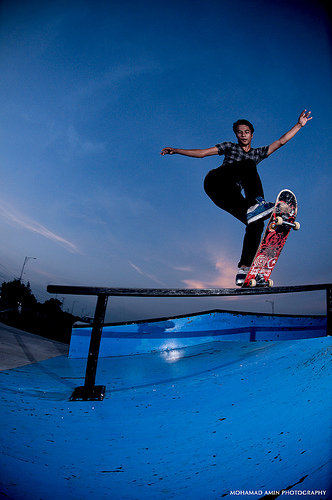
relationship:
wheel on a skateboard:
[274, 214, 283, 227] [243, 186, 298, 285]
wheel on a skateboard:
[292, 221, 299, 231] [243, 186, 298, 285]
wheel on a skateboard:
[264, 277, 276, 292] [243, 186, 298, 285]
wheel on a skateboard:
[247, 277, 259, 290] [243, 186, 298, 285]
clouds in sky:
[7, 185, 245, 291] [8, 10, 315, 291]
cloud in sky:
[61, 82, 105, 155] [1, 3, 330, 336]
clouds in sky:
[0, 185, 245, 301] [8, 9, 146, 263]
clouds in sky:
[0, 185, 245, 301] [1, 3, 330, 336]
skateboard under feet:
[158, 108, 314, 285] [244, 195, 275, 224]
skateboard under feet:
[158, 108, 314, 285] [235, 270, 275, 288]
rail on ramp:
[42, 275, 330, 327] [43, 263, 329, 419]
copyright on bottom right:
[223, 480, 330, 498] [200, 472, 329, 498]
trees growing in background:
[4, 276, 95, 348] [1, 222, 327, 360]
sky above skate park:
[0, 0, 332, 290] [12, 195, 330, 405]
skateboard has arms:
[241, 188, 301, 289] [152, 106, 330, 162]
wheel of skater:
[293, 221, 301, 231] [155, 79, 327, 297]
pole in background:
[17, 254, 38, 278] [2, 237, 328, 367]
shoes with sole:
[226, 203, 308, 258] [228, 276, 276, 289]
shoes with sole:
[226, 203, 308, 258] [240, 208, 291, 228]